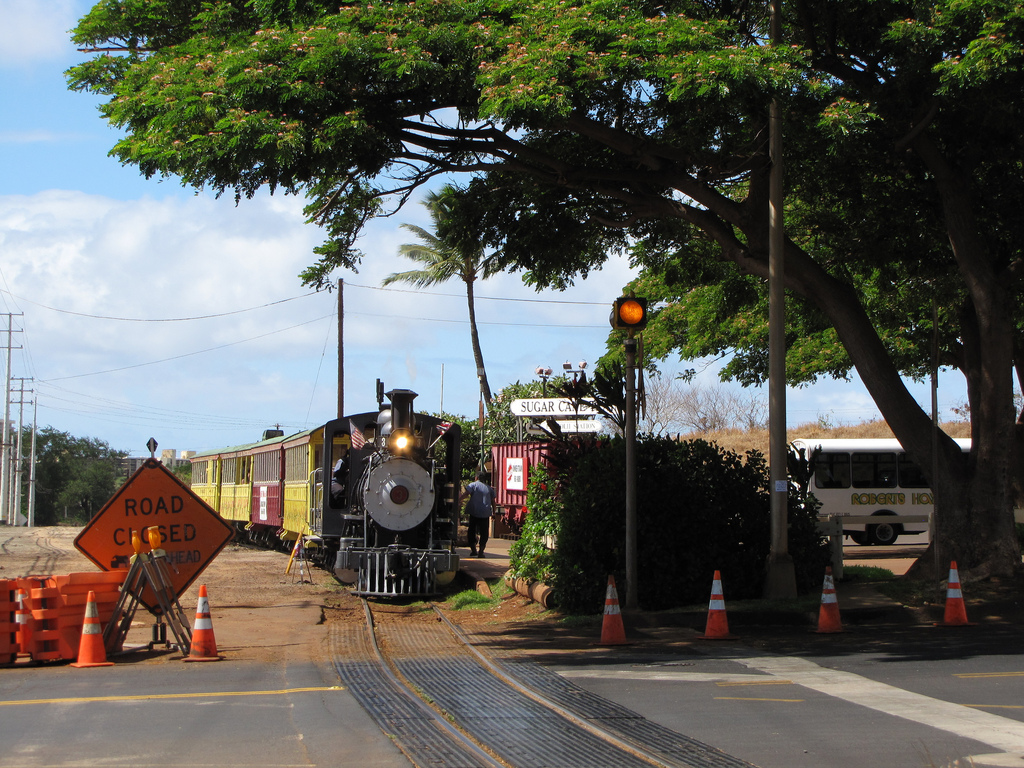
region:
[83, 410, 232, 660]
this is an orange road sign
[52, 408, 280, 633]
a road closed sign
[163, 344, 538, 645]
this is a train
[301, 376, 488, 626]
this is the engine car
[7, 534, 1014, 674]
these are orange and white street cones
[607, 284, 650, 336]
this is an orange light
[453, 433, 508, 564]
this person is next to the train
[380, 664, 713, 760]
this is a train crossing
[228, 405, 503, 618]
yellow train engine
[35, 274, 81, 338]
white clouds in the blue sky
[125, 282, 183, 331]
white clouds in the blue sky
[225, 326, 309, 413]
white clouds in the blue sky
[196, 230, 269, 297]
white clouds in the blue sky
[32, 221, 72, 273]
white clouds in the blue sky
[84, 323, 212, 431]
white clouds in the blue sky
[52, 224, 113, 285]
white clouds in the blue sky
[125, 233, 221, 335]
white clouds in the blue sky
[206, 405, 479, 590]
yellow and black train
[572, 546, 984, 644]
orange and white safety cones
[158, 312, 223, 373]
white clouds in blue sky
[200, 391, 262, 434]
white clouds in blue sky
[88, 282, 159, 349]
white clouds in blue sky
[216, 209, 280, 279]
white clouds in blue sky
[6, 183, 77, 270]
white clouds in blue sky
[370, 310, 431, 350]
white clouds in blue sky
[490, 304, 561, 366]
white clouds in blue sky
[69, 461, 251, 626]
orange sign with black lettering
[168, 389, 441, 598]
train traveling on the tracks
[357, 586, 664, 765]
tracks the train is traveling on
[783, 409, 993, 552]
white bus with black windows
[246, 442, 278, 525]
red train car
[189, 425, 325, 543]
three yellow train cars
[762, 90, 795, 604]
tall gray pole by the train tracks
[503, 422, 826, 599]
bushes by the train tracks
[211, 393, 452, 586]
yellow train on tracks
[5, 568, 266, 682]
orange safety cones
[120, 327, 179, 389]
white clouds in the blue sky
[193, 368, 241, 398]
white clouds in the blue sky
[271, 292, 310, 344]
white clouds in the blue sky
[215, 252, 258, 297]
white clouds in the blue sky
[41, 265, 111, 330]
white clouds in the blue sky